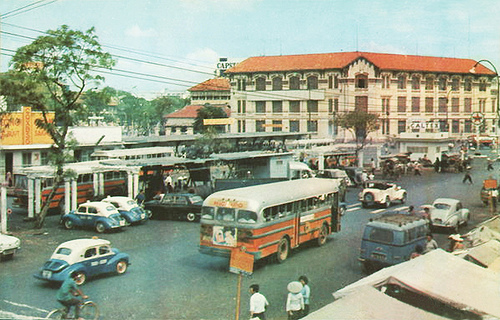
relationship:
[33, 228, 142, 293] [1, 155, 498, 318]
car on street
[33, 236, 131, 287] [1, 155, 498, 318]
car on street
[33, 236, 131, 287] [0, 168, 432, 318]
car passing by in street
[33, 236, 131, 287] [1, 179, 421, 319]
car passing by in street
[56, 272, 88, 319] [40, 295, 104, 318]
man riding bike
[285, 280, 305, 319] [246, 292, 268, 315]
people wearing a shirt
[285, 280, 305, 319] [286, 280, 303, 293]
people wearing a hat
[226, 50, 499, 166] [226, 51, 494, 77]
building with a roof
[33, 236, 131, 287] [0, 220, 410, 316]
car in street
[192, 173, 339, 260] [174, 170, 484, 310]
bus on road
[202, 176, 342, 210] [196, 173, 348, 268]
top on bus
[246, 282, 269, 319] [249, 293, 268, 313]
man with a shirt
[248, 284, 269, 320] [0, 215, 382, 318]
man standing by a road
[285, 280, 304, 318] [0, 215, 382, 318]
people standing by a road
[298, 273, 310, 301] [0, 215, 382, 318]
people standing by a road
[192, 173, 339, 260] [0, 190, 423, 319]
bus on a road way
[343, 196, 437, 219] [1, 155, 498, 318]
lines painted on a street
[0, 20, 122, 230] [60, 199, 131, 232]
tree by car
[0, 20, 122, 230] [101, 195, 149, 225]
tree by car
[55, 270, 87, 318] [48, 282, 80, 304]
man wearing a shirt